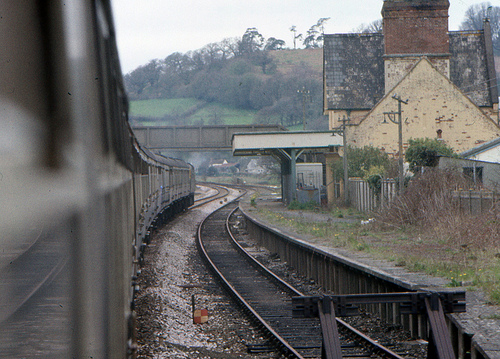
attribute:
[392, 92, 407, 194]
power pole — brown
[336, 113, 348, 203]
power pole — brown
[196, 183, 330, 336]
train tracks — empty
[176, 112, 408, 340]
tracks — train tracks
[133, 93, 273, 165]
terrain — elevated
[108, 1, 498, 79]
sky — hazy, gray, overcast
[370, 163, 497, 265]
brush — dried-out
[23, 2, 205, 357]
train cars — line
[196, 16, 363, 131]
trees — green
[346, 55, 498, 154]
house`s top —  triangular shaped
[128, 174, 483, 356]
tracks — windy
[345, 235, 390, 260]
dirt — sparse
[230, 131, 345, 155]
awning — white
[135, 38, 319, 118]
trees — in the distance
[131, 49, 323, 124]
hill — tree covered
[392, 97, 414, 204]
poles — old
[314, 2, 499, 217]
brick building — old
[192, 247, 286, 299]
tracks — curvy, railroad tracks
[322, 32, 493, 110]
roof — slants at angle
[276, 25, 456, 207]
building — tan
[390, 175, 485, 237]
bushes — dead